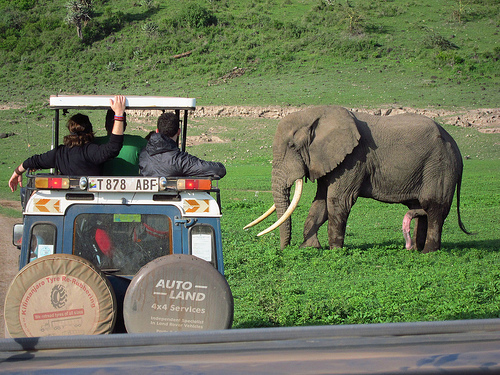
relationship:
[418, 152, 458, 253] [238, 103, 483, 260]
leg of elephant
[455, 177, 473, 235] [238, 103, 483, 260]
tail of elephant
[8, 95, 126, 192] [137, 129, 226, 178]
people wearing windbreaker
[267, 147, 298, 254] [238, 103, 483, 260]
trunk on elephant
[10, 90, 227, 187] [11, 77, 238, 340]
people in vehicle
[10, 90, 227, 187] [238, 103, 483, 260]
people watching elephant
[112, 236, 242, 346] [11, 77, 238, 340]
wheel of vehicle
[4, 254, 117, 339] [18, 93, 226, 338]
wheel on back of vehicle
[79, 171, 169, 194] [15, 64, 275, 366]
license tag on vehicle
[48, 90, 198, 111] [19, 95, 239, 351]
top of vehicle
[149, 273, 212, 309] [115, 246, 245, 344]
advertisement on wheel cover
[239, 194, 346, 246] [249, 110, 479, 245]
tusks on elephant